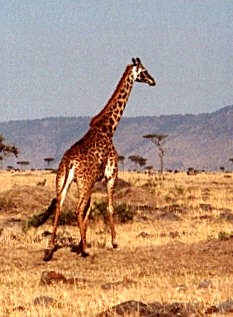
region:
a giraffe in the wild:
[34, 51, 154, 267]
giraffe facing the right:
[90, 52, 163, 134]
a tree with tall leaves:
[139, 127, 182, 179]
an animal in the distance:
[31, 175, 48, 189]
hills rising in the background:
[0, 104, 232, 170]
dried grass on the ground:
[98, 273, 224, 302]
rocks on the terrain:
[93, 271, 193, 315]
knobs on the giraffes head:
[127, 53, 146, 68]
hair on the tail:
[21, 192, 61, 232]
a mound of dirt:
[97, 181, 161, 210]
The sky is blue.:
[30, 26, 95, 72]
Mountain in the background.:
[10, 109, 231, 163]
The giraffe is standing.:
[25, 54, 156, 260]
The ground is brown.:
[118, 251, 183, 295]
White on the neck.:
[128, 64, 141, 80]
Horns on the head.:
[128, 53, 146, 64]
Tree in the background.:
[138, 126, 171, 175]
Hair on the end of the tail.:
[28, 192, 61, 229]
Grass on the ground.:
[86, 197, 132, 224]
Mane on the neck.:
[83, 64, 135, 123]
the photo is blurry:
[3, 1, 232, 306]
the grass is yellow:
[137, 248, 211, 312]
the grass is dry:
[149, 244, 216, 296]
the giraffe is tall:
[31, 53, 166, 272]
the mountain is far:
[155, 104, 231, 170]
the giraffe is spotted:
[12, 48, 155, 229]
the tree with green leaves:
[140, 131, 170, 180]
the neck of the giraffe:
[89, 78, 154, 148]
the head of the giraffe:
[128, 56, 161, 89]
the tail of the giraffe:
[39, 163, 78, 207]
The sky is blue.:
[10, 11, 82, 78]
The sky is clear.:
[22, 18, 94, 77]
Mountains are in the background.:
[0, 97, 232, 178]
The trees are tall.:
[133, 126, 173, 172]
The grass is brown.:
[141, 223, 207, 280]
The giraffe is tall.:
[28, 54, 160, 262]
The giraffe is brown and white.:
[24, 53, 164, 261]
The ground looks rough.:
[126, 184, 217, 243]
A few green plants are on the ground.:
[211, 225, 232, 244]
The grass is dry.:
[133, 228, 199, 284]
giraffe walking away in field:
[37, 49, 167, 284]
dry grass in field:
[152, 208, 186, 264]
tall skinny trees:
[135, 114, 181, 198]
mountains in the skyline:
[174, 81, 223, 175]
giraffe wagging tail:
[28, 154, 84, 232]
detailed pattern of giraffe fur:
[70, 144, 105, 182]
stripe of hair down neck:
[80, 47, 167, 140]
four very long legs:
[37, 167, 127, 265]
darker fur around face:
[137, 66, 158, 91]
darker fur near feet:
[106, 233, 122, 253]